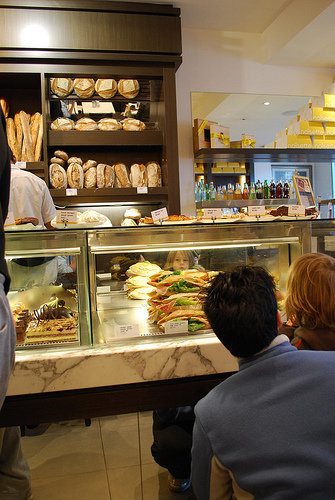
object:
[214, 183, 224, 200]
bottle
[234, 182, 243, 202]
bottle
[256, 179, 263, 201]
bottle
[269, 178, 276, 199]
bottle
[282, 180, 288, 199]
bottle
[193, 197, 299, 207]
counter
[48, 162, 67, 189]
bread loaves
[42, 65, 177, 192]
display shelf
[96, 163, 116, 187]
bread loaves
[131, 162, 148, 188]
bread loaves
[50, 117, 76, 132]
bread loaves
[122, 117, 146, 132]
bread loaves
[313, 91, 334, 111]
boxes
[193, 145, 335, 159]
shelf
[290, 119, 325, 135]
boxes